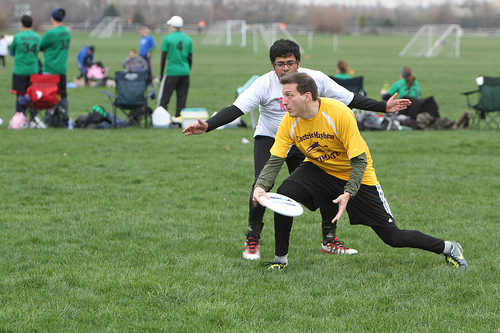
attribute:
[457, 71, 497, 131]
chair — green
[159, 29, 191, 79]
shirt — green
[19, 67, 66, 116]
chair — red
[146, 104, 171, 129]
cooler — blue, white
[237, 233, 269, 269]
tennis shoe — white, red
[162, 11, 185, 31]
hat — white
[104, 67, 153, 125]
chair — blue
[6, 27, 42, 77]
shirt — green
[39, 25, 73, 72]
shirt — green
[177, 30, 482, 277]
people — playing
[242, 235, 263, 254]
laces — red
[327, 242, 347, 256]
laces — red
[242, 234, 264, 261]
sneaker — white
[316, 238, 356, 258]
sneaker — white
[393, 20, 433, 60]
goal post — white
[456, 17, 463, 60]
goal post — white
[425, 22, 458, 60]
goal post — white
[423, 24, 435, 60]
goal post — white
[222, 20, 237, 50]
goal post — white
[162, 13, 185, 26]
cap — white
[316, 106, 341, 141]
stripe — white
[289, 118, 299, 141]
stripe — white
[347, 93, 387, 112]
shirt sleeve — black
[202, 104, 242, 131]
shirt sleeve — black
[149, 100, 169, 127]
cooler — white and blue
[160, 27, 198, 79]
shirt — green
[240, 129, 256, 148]
paper — white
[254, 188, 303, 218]
frisbee — white, round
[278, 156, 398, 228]
shorts — black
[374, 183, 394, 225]
stripe — white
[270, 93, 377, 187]
shirt — yellow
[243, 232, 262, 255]
lace — red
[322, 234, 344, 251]
lace — red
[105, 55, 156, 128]
chair — portable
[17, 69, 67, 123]
chair — portable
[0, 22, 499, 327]
field — beautiful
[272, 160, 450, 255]
pants — black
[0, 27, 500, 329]
grass — green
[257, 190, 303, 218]
frisbee — white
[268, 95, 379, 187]
pullover — yellow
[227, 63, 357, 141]
shirt — white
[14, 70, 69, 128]
lawn chair — red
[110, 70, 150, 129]
lawn chair — navy blue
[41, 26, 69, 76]
jersey — dark green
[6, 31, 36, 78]
jersey — dark green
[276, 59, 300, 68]
glasses — black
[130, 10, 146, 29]
pine tree — green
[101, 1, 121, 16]
pine tree — green